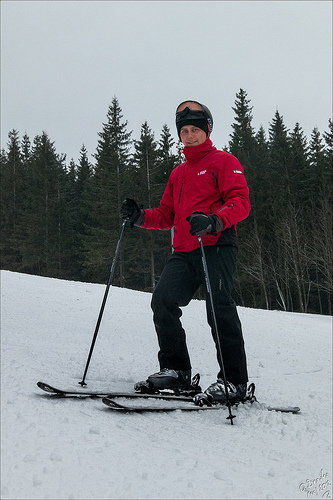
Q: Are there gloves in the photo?
A: Yes, there are gloves.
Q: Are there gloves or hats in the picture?
A: Yes, there are gloves.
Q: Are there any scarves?
A: No, there are no scarves.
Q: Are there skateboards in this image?
A: No, there are no skateboards.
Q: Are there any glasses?
A: No, there are no glasses.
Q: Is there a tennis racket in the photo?
A: No, there are no rackets.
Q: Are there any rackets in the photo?
A: No, there are no rackets.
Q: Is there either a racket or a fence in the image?
A: No, there are no rackets or fences.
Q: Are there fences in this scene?
A: No, there are no fences.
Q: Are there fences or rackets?
A: No, there are no fences or rackets.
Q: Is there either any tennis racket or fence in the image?
A: No, there are no fences or rackets.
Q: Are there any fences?
A: No, there are no fences.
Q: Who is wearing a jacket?
A: The man is wearing a jacket.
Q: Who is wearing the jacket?
A: The man is wearing a jacket.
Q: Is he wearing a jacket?
A: Yes, the man is wearing a jacket.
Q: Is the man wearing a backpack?
A: No, the man is wearing a jacket.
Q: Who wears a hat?
A: The man wears a hat.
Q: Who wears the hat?
A: The man wears a hat.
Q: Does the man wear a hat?
A: Yes, the man wears a hat.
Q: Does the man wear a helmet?
A: No, the man wears a hat.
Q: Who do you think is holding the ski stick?
A: The man is holding the stick.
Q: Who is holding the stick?
A: The man is holding the stick.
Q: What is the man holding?
A: The man is holding the stick.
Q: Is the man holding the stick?
A: Yes, the man is holding the stick.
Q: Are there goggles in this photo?
A: Yes, there are goggles.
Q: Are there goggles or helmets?
A: Yes, there are goggles.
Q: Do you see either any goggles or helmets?
A: Yes, there are goggles.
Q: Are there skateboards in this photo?
A: No, there are no skateboards.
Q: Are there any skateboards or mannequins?
A: No, there are no skateboards or mannequins.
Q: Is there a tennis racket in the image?
A: No, there are no rackets.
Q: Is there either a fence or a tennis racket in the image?
A: No, there are no rackets or fences.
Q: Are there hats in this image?
A: Yes, there is a hat.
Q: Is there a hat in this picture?
A: Yes, there is a hat.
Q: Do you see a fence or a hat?
A: Yes, there is a hat.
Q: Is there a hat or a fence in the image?
A: Yes, there is a hat.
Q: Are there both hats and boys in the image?
A: No, there is a hat but no boys.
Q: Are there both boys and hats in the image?
A: No, there is a hat but no boys.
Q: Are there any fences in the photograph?
A: No, there are no fences.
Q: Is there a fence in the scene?
A: No, there are no fences.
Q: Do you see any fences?
A: No, there are no fences.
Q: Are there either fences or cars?
A: No, there are no fences or cars.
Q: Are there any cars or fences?
A: No, there are no fences or cars.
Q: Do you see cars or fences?
A: No, there are no fences or cars.